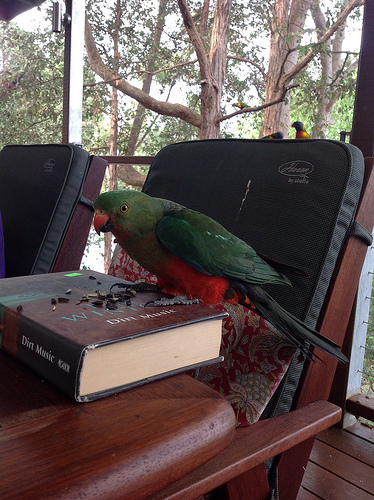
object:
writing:
[22, 335, 70, 373]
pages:
[79, 319, 222, 396]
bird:
[94, 190, 350, 366]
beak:
[93, 211, 112, 236]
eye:
[120, 204, 128, 213]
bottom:
[162, 258, 239, 304]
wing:
[155, 215, 293, 289]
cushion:
[107, 243, 298, 428]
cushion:
[141, 139, 365, 421]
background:
[0, 0, 373, 427]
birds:
[260, 132, 283, 139]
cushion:
[0, 143, 90, 278]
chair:
[0, 145, 109, 280]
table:
[0, 346, 236, 500]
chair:
[106, 137, 373, 500]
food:
[16, 275, 135, 313]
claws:
[110, 281, 161, 292]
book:
[0, 270, 230, 403]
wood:
[0, 155, 374, 500]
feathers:
[232, 278, 349, 366]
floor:
[294, 426, 373, 500]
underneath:
[121, 243, 220, 301]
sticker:
[64, 273, 83, 278]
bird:
[232, 102, 251, 110]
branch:
[217, 83, 301, 124]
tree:
[84, 0, 301, 139]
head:
[93, 190, 141, 237]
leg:
[144, 295, 203, 308]